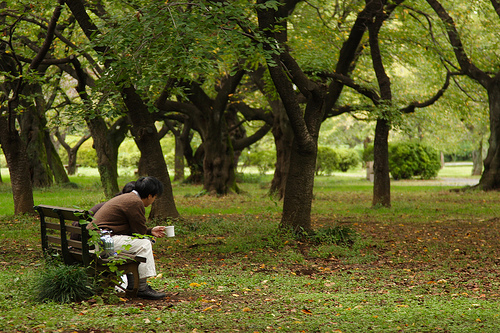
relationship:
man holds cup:
[104, 156, 189, 261] [158, 203, 183, 228]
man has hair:
[104, 156, 189, 261] [136, 174, 163, 199]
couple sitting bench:
[69, 174, 167, 299] [32, 202, 147, 297]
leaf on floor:
[437, 278, 446, 283] [0, 132, 497, 332]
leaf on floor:
[401, 267, 412, 272] [0, 132, 497, 332]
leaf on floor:
[452, 247, 461, 252] [0, 132, 497, 332]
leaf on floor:
[408, 257, 413, 262] [0, 132, 497, 332]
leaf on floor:
[422, 245, 427, 251] [0, 132, 497, 332]